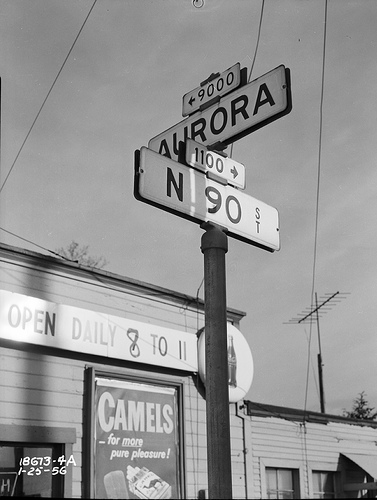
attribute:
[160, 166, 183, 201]
letter — black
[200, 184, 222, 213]
letter — black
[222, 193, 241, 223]
letter — black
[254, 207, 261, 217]
letter — black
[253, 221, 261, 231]
letter — black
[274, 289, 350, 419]
antennae — old fashioned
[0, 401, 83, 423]
siding — aluminum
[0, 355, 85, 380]
siding — aluminum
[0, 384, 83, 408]
siding — aluminum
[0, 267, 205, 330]
siding — aluminum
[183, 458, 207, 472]
siding — aluminum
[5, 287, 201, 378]
sign — mounted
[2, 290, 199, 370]
sign — white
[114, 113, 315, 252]
sign — street sign, N 90 ST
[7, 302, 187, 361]
letters — black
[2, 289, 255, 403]
sign — white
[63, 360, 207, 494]
poster — advertising cigarettes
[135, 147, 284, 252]
sign — white, north 90th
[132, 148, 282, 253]
street sign — N 90 ST